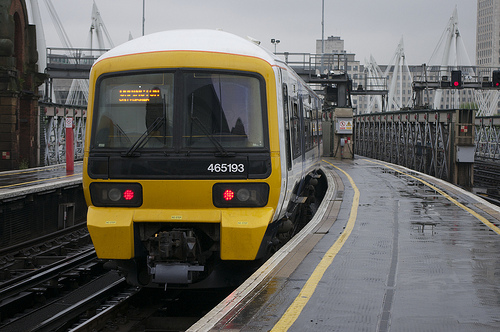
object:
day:
[1, 1, 496, 328]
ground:
[218, 143, 497, 327]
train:
[85, 28, 327, 288]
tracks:
[5, 219, 189, 330]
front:
[84, 50, 277, 256]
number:
[206, 163, 215, 173]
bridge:
[41, 45, 488, 84]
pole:
[64, 114, 76, 174]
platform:
[0, 155, 82, 197]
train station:
[4, 27, 499, 322]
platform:
[233, 149, 494, 332]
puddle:
[400, 180, 441, 201]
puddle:
[412, 215, 440, 229]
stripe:
[267, 161, 361, 330]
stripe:
[368, 153, 500, 239]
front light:
[213, 181, 269, 207]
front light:
[89, 182, 143, 209]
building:
[473, 2, 499, 167]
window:
[93, 74, 264, 176]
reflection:
[100, 75, 250, 173]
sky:
[33, 4, 479, 56]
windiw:
[292, 87, 300, 156]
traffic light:
[448, 69, 465, 90]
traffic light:
[490, 69, 500, 87]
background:
[418, 2, 497, 136]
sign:
[65, 117, 73, 129]